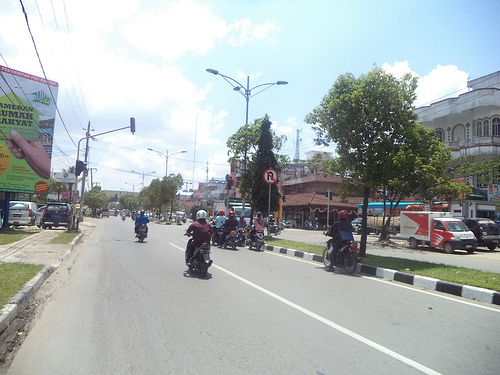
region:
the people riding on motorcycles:
[115, 205, 360, 278]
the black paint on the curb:
[393, 271, 412, 285]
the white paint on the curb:
[413, 275, 438, 290]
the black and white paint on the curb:
[260, 240, 498, 306]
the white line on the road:
[168, 235, 442, 374]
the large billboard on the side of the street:
[0, 65, 56, 191]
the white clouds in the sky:
[0, 0, 498, 190]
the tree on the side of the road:
[301, 60, 496, 255]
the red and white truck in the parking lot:
[395, 211, 478, 252]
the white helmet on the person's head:
[195, 208, 205, 218]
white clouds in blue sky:
[39, 11, 122, 62]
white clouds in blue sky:
[86, 47, 159, 109]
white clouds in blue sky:
[132, 134, 178, 157]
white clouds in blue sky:
[169, 97, 211, 141]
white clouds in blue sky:
[107, 9, 178, 98]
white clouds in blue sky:
[173, 11, 265, 53]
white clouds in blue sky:
[266, 13, 339, 70]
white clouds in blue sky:
[377, 18, 480, 73]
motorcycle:
[178, 208, 222, 279]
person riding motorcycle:
[137, 197, 154, 248]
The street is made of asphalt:
[80, 310, 300, 372]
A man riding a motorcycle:
[177, 204, 221, 284]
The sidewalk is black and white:
[372, 260, 494, 314]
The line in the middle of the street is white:
[266, 282, 395, 367]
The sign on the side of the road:
[259, 156, 283, 243]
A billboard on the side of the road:
[0, 53, 80, 208]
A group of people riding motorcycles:
[206, 204, 272, 252]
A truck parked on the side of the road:
[396, 198, 477, 251]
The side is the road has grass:
[377, 254, 499, 293]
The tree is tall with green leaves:
[302, 66, 465, 250]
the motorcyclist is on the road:
[181, 209, 211, 276]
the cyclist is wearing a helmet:
[195, 208, 209, 220]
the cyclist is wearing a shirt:
[189, 219, 210, 244]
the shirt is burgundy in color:
[186, 219, 212, 242]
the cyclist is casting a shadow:
[183, 264, 213, 280]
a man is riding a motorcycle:
[183, 210, 214, 270]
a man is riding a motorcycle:
[133, 209, 150, 240]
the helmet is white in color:
[195, 210, 206, 218]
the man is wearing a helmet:
[218, 208, 225, 215]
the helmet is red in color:
[218, 208, 225, 217]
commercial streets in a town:
[10, 15, 477, 360]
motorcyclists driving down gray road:
[110, 190, 355, 280]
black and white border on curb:
[250, 235, 495, 300]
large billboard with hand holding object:
[0, 51, 60, 196]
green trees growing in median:
[230, 67, 466, 262]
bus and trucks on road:
[346, 192, 493, 247]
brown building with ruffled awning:
[280, 166, 356, 228]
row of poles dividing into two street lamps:
[116, 62, 286, 199]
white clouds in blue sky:
[2, 1, 494, 186]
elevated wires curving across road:
[3, 1, 234, 189]